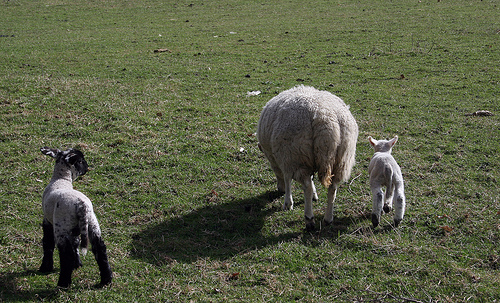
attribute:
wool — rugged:
[256, 85, 360, 190]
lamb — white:
[362, 128, 410, 237]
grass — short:
[95, 79, 218, 200]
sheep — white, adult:
[255, 82, 357, 222]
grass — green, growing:
[305, 21, 441, 77]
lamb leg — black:
[57, 246, 73, 295]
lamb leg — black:
[90, 237, 112, 289]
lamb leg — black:
[40, 231, 56, 276]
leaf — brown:
[246, 91, 266, 98]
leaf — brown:
[224, 23, 249, 40]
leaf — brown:
[456, 100, 498, 128]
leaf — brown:
[192, 46, 210, 61]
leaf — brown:
[152, 43, 169, 56]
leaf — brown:
[204, 24, 220, 46]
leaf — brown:
[240, 66, 269, 83]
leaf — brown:
[395, 69, 415, 89]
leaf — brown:
[282, 23, 297, 42]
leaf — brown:
[334, 72, 355, 87]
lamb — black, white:
[33, 137, 116, 289]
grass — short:
[191, 20, 290, 82]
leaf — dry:
[153, 46, 170, 54]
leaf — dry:
[210, 32, 220, 39]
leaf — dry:
[228, 30, 238, 35]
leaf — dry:
[439, 223, 452, 232]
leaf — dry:
[471, 108, 492, 118]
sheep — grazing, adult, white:
[250, 79, 362, 228]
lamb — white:
[365, 133, 407, 231]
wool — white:
[44, 184, 71, 226]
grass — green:
[46, 21, 445, 269]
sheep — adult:
[252, 80, 406, 237]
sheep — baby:
[364, 132, 407, 228]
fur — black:
[37, 215, 55, 274]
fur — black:
[88, 232, 113, 287]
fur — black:
[56, 235, 77, 289]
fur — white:
[256, 82, 361, 229]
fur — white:
[363, 130, 405, 227]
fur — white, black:
[38, 146, 114, 291]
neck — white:
[47, 161, 73, 185]